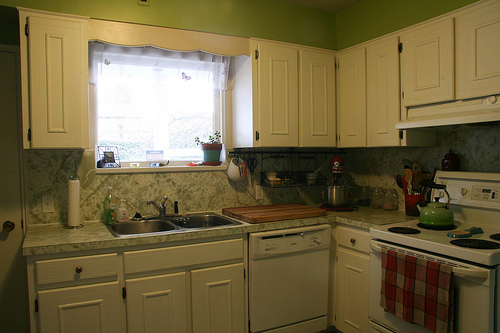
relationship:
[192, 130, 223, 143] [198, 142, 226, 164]
flowers in a vase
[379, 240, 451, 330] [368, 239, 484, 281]
towel over door handle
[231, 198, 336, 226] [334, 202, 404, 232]
board on top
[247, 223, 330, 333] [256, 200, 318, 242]
dishwasher under counter top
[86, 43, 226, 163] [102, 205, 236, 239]
window above sink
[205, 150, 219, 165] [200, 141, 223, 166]
paint on vase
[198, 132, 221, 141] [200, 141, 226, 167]
flowers are in flower pot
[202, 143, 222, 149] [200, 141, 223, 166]
paint on vase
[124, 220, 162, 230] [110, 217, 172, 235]
inside of sink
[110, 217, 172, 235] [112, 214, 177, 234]
sink on left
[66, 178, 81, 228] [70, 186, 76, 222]
paper towels of towel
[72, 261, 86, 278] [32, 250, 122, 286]
knob on drawer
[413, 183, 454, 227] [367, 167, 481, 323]
kettle on stove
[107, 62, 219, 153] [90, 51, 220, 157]
light coming through window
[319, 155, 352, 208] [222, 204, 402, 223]
mixer on counter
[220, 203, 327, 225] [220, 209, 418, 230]
board on counter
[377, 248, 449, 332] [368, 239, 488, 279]
towel on door handle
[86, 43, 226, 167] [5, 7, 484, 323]
window in kitchen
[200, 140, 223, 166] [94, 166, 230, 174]
vase on window sill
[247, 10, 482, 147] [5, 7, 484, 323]
cabinets in kitchen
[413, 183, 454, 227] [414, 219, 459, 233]
kettle on a burner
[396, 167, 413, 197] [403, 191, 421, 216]
utensils in a utensil holder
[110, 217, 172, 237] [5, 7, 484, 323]
sink in kitchen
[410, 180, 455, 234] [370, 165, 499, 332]
kettle on stove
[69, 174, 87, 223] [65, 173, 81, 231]
paper towels on holder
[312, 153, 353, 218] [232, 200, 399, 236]
mixer on counter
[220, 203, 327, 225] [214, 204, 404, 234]
board on counter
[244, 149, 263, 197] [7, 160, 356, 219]
scissors hanging on wall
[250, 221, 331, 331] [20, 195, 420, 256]
dishwasher under kitchen counter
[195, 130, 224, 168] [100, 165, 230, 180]
plant on window sill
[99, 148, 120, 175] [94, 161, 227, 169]
picture on window sill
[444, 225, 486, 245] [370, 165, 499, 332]
spoon holder on stove